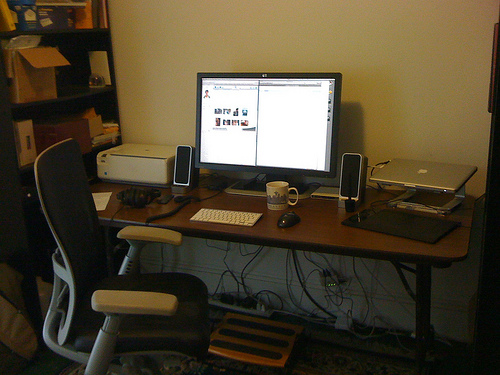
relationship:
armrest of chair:
[90, 279, 192, 326] [27, 106, 228, 365]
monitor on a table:
[191, 68, 342, 198] [82, 154, 474, 364]